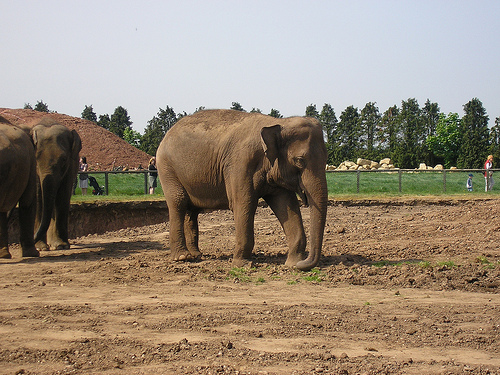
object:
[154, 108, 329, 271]
elephant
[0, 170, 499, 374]
ground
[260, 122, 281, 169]
ear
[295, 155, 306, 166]
eye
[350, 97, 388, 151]
trees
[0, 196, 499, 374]
dirt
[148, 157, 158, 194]
woman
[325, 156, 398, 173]
rocks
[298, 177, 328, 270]
trunk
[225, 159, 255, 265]
leg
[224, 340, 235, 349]
rock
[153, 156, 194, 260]
leg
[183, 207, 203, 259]
leg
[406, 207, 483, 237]
part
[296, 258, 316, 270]
part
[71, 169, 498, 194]
fence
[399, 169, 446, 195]
part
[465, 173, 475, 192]
child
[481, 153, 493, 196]
adult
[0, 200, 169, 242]
mound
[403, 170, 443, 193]
grass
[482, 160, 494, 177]
jacket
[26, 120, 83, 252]
elephant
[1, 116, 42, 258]
elephant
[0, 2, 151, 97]
sky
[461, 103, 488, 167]
leaves